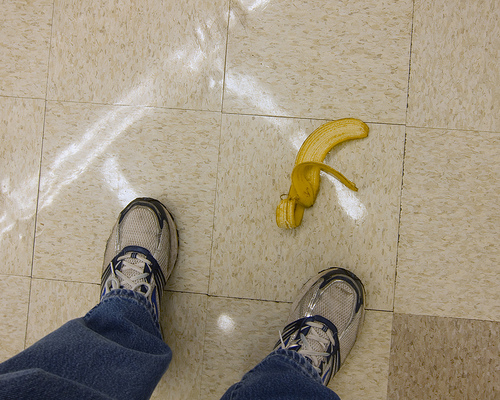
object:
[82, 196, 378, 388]
footwear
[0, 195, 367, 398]
person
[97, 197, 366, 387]
shoes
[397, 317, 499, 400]
tiles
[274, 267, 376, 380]
foot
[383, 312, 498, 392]
tile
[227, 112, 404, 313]
floor tiles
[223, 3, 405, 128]
floor tiles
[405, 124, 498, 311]
floor tiles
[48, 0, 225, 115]
floor tiles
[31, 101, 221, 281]
floor tiles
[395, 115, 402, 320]
edge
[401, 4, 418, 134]
edge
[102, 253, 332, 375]
shoe laces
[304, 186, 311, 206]
mark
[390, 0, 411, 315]
lines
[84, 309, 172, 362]
wrinkle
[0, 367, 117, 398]
wrinkle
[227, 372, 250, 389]
wrinkle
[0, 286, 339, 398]
jeans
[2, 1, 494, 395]
tile flooring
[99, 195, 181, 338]
left shoe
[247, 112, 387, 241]
banana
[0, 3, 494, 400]
floor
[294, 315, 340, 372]
laces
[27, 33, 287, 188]
sunlit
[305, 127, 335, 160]
interior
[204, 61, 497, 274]
ground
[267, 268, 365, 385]
shoe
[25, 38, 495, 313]
ground